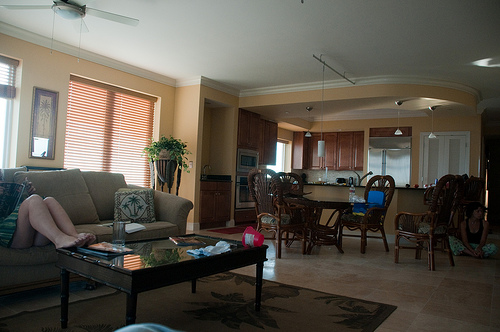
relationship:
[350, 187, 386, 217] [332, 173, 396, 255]
baby seat next in baby chair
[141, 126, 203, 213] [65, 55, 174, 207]
plant by window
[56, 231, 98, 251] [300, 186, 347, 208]
feet on table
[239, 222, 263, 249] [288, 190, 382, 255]
object on table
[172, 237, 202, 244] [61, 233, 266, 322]
booklet on table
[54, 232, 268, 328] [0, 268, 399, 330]
coffee table on rug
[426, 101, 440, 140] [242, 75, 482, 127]
light on ceiling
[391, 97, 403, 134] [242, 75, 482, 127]
light on ceiling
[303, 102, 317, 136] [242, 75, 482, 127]
light on ceiling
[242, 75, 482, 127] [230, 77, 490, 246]
ceiling in kitchen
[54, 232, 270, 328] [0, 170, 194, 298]
coffee table fronting couch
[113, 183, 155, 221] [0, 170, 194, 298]
pillow on couch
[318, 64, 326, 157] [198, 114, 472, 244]
light fixture in kitchen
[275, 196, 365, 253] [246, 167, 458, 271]
table with chairs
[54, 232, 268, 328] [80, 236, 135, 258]
coffee table with magazines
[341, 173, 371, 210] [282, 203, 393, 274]
bottle on table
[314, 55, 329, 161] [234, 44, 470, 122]
light fixture on ceiling